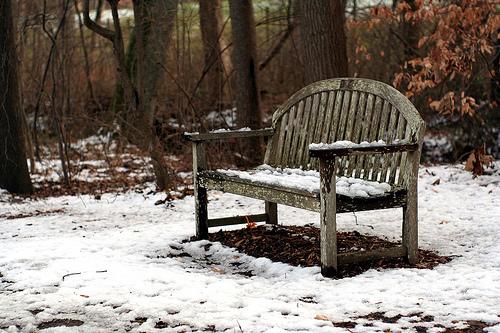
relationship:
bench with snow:
[183, 78, 427, 276] [218, 162, 391, 199]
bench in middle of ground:
[183, 78, 427, 276] [0, 106, 500, 333]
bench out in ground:
[183, 78, 427, 276] [0, 106, 500, 333]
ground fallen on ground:
[0, 106, 500, 333] [0, 106, 499, 332]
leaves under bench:
[208, 224, 448, 273] [183, 78, 427, 276]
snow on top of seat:
[218, 162, 391, 199] [198, 166, 408, 214]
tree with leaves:
[294, 1, 350, 93] [347, 1, 498, 114]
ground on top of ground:
[0, 106, 500, 333] [0, 106, 499, 332]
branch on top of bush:
[92, 117, 132, 144] [78, 109, 224, 185]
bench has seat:
[183, 78, 427, 276] [198, 166, 408, 214]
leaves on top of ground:
[208, 224, 448, 273] [0, 106, 499, 332]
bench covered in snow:
[183, 78, 427, 276] [218, 162, 391, 199]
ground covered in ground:
[0, 106, 499, 332] [0, 106, 500, 333]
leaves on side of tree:
[347, 1, 498, 114] [294, 1, 350, 93]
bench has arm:
[183, 78, 427, 276] [308, 140, 419, 194]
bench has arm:
[183, 78, 427, 276] [183, 127, 273, 170]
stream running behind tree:
[74, 0, 432, 24] [294, 1, 350, 93]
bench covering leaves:
[183, 78, 427, 276] [208, 224, 448, 273]